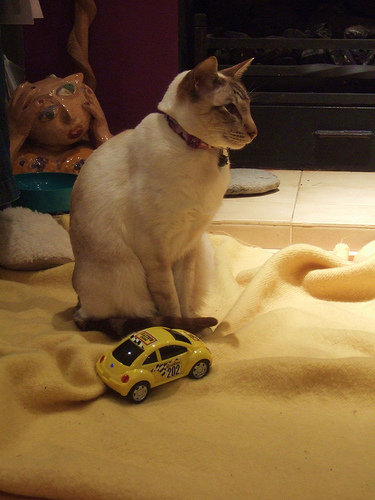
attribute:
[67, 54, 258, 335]
cat — sitting, white, tan, siamese, staring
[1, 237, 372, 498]
blanket — yellow, wrinkled, coloured, colored, cream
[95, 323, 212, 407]
beetle — yellow, little, toy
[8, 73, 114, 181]
statue — bizzare, piccaso-esque, ceramic, strange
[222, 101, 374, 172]
drawer — wooden, painted, black, green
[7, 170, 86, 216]
bowl — teal, shiny, plastic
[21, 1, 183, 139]
wall — painted, burgundy, purple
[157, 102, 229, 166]
collar — purple, small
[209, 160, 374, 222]
floor — white, tiled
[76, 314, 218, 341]
tail — striped, brown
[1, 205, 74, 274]
pillow — fluffy, white